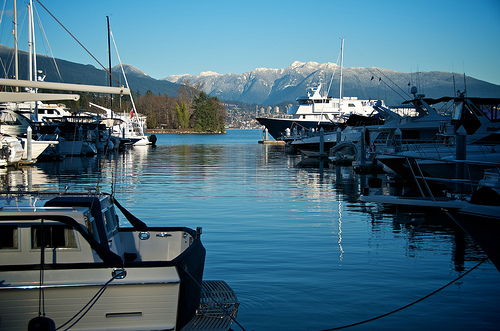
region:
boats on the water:
[236, 48, 495, 264]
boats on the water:
[8, 31, 173, 218]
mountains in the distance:
[183, 53, 464, 113]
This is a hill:
[174, 48, 224, 96]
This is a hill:
[209, 59, 257, 104]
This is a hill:
[243, 57, 293, 114]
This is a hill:
[283, 48, 326, 109]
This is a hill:
[290, 51, 344, 113]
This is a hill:
[346, 45, 393, 99]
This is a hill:
[426, 48, 466, 87]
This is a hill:
[176, 56, 220, 108]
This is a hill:
[239, 53, 277, 103]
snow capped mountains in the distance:
[188, 52, 341, 77]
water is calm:
[178, 130, 268, 236]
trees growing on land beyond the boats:
[153, 86, 225, 132]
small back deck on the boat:
[198, 275, 230, 326]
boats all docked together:
[260, 90, 490, 235]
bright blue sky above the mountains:
[133, 19, 303, 46]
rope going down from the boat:
[192, 278, 247, 328]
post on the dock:
[316, 124, 326, 154]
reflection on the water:
[273, 148, 326, 205]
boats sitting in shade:
[386, 115, 489, 220]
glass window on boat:
[3, 227, 19, 250]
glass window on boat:
[33, 223, 73, 248]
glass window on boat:
[101, 212, 114, 229]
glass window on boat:
[36, 105, 43, 112]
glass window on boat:
[45, 108, 55, 113]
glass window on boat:
[347, 103, 357, 110]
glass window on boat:
[311, 97, 323, 104]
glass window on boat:
[320, 98, 330, 105]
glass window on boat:
[294, 98, 313, 104]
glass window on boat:
[451, 102, 462, 118]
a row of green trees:
[2, 84, 233, 131]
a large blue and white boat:
[248, 35, 435, 144]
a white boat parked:
[0, 184, 250, 328]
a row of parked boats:
[244, 39, 499, 299]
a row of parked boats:
[3, 2, 243, 326]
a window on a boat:
[23, 216, 82, 251]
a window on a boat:
[295, 96, 310, 107]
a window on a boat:
[0, 227, 20, 254]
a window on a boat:
[36, 107, 44, 114]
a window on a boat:
[46, 108, 55, 115]